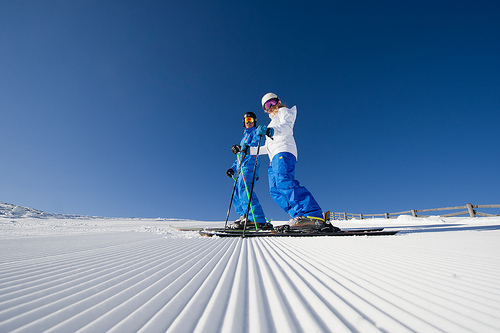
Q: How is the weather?
A: It is clear.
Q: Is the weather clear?
A: Yes, it is clear.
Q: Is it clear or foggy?
A: It is clear.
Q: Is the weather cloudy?
A: No, it is clear.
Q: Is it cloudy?
A: No, it is clear.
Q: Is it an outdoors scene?
A: Yes, it is outdoors.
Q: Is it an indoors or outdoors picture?
A: It is outdoors.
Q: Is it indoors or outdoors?
A: It is outdoors.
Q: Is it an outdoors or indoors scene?
A: It is outdoors.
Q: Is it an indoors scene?
A: No, it is outdoors.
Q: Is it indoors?
A: No, it is outdoors.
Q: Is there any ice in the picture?
A: Yes, there is ice.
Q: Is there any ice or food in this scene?
A: Yes, there is ice.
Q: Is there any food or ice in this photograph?
A: Yes, there is ice.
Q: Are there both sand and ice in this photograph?
A: No, there is ice but no sand.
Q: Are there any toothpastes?
A: No, there are no toothpastes.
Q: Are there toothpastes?
A: No, there are no toothpastes.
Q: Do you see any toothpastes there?
A: No, there are no toothpastes.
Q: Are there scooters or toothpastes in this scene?
A: No, there are no toothpastes or scooters.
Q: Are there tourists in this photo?
A: No, there are no tourists.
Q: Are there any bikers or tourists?
A: No, there are no tourists or bikers.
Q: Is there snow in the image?
A: Yes, there is snow.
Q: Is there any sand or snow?
A: Yes, there is snow.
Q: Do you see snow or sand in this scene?
A: Yes, there is snow.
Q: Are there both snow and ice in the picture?
A: Yes, there are both snow and ice.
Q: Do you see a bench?
A: No, there are no benches.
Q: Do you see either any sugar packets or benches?
A: No, there are no benches or sugar packets.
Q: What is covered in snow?
A: The ground is covered in snow.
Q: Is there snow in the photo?
A: Yes, there is snow.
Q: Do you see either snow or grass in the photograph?
A: Yes, there is snow.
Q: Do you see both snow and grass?
A: No, there is snow but no grass.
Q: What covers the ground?
A: The snow covers the ground.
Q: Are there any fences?
A: Yes, there is a fence.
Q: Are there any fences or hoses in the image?
A: Yes, there is a fence.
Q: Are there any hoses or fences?
A: Yes, there is a fence.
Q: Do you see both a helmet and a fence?
A: Yes, there are both a fence and a helmet.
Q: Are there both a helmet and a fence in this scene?
A: Yes, there are both a fence and a helmet.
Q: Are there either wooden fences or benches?
A: Yes, there is a wood fence.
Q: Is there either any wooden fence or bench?
A: Yes, there is a wood fence.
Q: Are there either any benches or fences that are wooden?
A: Yes, the fence is wooden.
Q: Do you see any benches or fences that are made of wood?
A: Yes, the fence is made of wood.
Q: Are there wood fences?
A: Yes, there is a wood fence.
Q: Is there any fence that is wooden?
A: Yes, there is a fence that is wooden.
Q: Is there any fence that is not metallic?
A: Yes, there is a wooden fence.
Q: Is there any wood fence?
A: Yes, there is a fence that is made of wood.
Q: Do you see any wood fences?
A: Yes, there is a fence that is made of wood.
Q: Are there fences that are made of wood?
A: Yes, there is a fence that is made of wood.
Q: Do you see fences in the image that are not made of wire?
A: Yes, there is a fence that is made of wood.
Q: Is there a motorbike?
A: No, there are no motorcycles.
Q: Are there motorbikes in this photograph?
A: No, there are no motorbikes.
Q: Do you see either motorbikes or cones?
A: No, there are no motorbikes or cones.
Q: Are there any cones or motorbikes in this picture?
A: No, there are no motorbikes or cones.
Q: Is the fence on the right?
A: Yes, the fence is on the right of the image.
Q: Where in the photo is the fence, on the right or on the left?
A: The fence is on the right of the image.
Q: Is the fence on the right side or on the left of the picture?
A: The fence is on the right of the image.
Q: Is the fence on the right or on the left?
A: The fence is on the right of the image.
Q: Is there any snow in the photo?
A: Yes, there is snow.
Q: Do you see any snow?
A: Yes, there is snow.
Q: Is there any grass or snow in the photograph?
A: Yes, there is snow.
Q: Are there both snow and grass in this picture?
A: No, there is snow but no grass.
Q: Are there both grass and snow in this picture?
A: No, there is snow but no grass.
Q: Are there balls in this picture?
A: No, there are no balls.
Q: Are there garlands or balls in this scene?
A: No, there are no balls or garlands.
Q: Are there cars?
A: No, there are no cars.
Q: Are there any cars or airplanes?
A: No, there are no cars or airplanes.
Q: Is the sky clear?
A: Yes, the sky is clear.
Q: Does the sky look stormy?
A: No, the sky is clear.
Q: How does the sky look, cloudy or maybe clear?
A: The sky is clear.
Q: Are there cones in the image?
A: No, there are no cones.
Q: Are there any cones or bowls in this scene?
A: No, there are no cones or bowls.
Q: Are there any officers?
A: No, there are no officers.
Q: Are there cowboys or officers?
A: No, there are no officers or cowboys.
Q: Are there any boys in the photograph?
A: No, there are no boys.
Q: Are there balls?
A: No, there are no balls.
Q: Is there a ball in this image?
A: No, there are no balls.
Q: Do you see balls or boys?
A: No, there are no balls or boys.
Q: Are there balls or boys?
A: No, there are no balls or boys.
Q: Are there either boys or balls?
A: No, there are no balls or boys.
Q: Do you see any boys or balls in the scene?
A: No, there are no balls or boys.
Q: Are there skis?
A: Yes, there are skis.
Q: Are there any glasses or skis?
A: Yes, there are skis.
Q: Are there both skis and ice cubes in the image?
A: No, there are skis but no ice cubes.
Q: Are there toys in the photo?
A: No, there are no toys.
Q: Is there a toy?
A: No, there are no toys.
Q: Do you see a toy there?
A: No, there are no toys.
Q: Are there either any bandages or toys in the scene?
A: No, there are no toys or bandages.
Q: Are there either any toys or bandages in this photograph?
A: No, there are no toys or bandages.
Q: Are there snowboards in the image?
A: No, there are no snowboards.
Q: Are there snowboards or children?
A: No, there are no snowboards or children.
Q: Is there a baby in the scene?
A: No, there are no babies.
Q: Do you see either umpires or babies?
A: No, there are no babies or umpires.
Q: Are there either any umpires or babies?
A: No, there are no babies or umpires.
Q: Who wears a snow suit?
A: The man wears a snow suit.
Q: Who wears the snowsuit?
A: The man wears a snow suit.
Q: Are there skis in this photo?
A: Yes, there are skis.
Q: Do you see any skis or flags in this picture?
A: Yes, there are skis.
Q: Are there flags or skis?
A: Yes, there are skis.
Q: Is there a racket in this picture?
A: No, there are no rackets.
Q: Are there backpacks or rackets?
A: No, there are no rackets or backpacks.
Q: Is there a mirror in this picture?
A: No, there are no mirrors.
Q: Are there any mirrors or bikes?
A: No, there are no mirrors or bikes.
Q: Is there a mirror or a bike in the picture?
A: No, there are no mirrors or bikes.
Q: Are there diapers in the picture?
A: No, there are no diapers.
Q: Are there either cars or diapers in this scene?
A: No, there are no diapers or cars.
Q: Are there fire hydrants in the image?
A: No, there are no fire hydrants.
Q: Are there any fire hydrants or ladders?
A: No, there are no fire hydrants or ladders.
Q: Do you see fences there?
A: Yes, there is a fence.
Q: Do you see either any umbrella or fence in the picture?
A: Yes, there is a fence.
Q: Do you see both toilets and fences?
A: No, there is a fence but no toilets.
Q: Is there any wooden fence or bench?
A: Yes, there is a wood fence.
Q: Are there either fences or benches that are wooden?
A: Yes, the fence is wooden.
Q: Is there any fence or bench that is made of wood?
A: Yes, the fence is made of wood.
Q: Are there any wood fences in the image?
A: Yes, there is a wood fence.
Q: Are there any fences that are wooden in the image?
A: Yes, there is a wood fence.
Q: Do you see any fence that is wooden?
A: Yes, there is a fence that is wooden.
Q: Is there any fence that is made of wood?
A: Yes, there is a fence that is made of wood.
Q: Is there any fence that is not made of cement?
A: Yes, there is a fence that is made of wood.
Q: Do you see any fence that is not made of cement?
A: Yes, there is a fence that is made of wood.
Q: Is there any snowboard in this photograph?
A: No, there are no snowboards.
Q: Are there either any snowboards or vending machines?
A: No, there are no snowboards or vending machines.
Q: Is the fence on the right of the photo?
A: Yes, the fence is on the right of the image.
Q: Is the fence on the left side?
A: No, the fence is on the right of the image.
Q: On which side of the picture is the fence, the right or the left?
A: The fence is on the right of the image.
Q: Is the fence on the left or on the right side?
A: The fence is on the right of the image.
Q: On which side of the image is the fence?
A: The fence is on the right of the image.